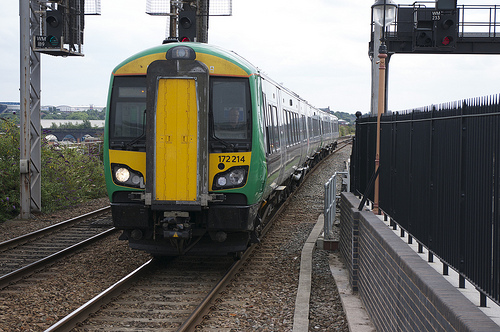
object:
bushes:
[0, 115, 107, 220]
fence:
[350, 92, 499, 309]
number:
[218, 155, 245, 162]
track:
[0, 203, 117, 284]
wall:
[340, 191, 499, 332]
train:
[103, 37, 340, 264]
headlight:
[110, 162, 145, 189]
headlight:
[211, 164, 250, 190]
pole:
[11, 0, 43, 217]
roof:
[79, 135, 106, 143]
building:
[41, 128, 104, 142]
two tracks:
[0, 205, 237, 329]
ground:
[0, 131, 354, 326]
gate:
[323, 172, 336, 239]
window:
[209, 77, 252, 153]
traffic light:
[435, 0, 459, 54]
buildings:
[85, 138, 106, 160]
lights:
[145, 0, 233, 16]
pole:
[368, 0, 389, 213]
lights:
[370, 0, 398, 27]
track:
[40, 253, 247, 332]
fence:
[378, 93, 500, 280]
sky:
[0, 5, 500, 117]